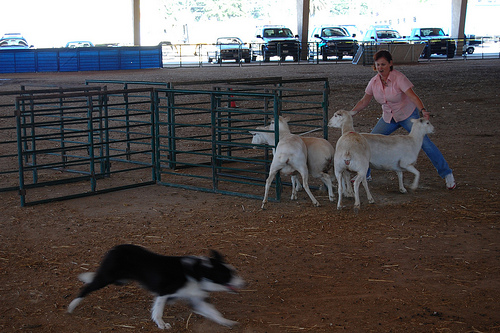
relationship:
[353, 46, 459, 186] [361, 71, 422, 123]
woman wearing shirt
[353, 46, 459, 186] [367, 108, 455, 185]
woman wearing jeans